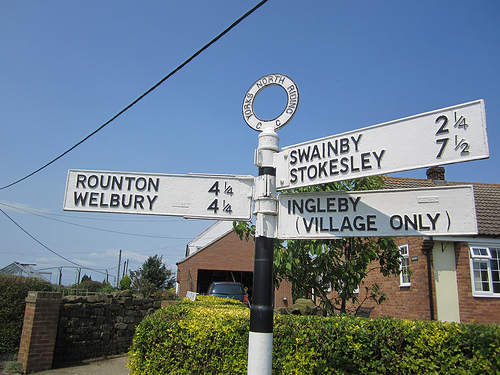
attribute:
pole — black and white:
[221, 171, 335, 373]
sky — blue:
[0, 0, 497, 286]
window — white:
[468, 244, 499, 301]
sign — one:
[56, 169, 253, 216]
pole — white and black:
[245, 240, 279, 374]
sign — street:
[56, 66, 499, 245]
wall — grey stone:
[47, 280, 161, 344]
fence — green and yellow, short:
[126, 289, 496, 374]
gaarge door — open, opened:
[194, 262, 261, 317]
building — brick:
[171, 164, 498, 332]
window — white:
[312, 257, 334, 294]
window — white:
[389, 243, 417, 290]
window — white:
[462, 239, 498, 299]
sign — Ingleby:
[277, 192, 476, 234]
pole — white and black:
[247, 147, 278, 371]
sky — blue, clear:
[338, 8, 496, 91]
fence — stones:
[53, 289, 179, 367]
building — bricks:
[192, 162, 467, 337]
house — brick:
[312, 180, 498, 318]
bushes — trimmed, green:
[127, 294, 496, 371]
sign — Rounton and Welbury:
[62, 165, 257, 227]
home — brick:
[177, 165, 497, 320]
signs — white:
[61, 72, 491, 240]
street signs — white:
[62, 95, 490, 244]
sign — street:
[272, 190, 475, 237]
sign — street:
[277, 101, 484, 183]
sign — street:
[58, 166, 250, 221]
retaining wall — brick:
[52, 300, 121, 368]